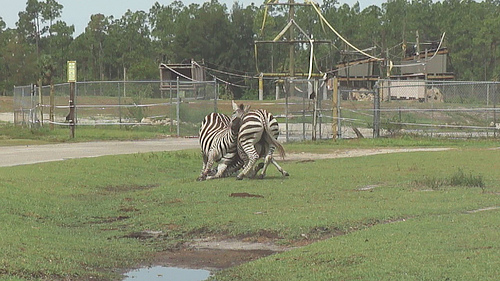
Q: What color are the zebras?
A: Black and white.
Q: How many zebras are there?
A: Two.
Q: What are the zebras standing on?
A: Grass.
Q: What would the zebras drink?
A: The water.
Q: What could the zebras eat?
A: The grass.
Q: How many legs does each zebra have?
A: Four.